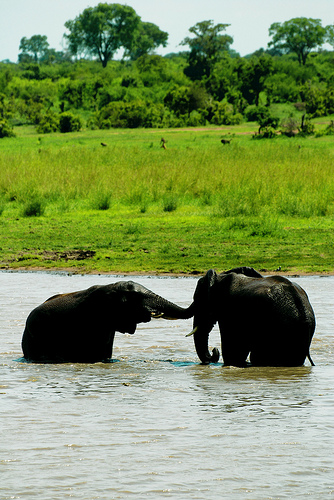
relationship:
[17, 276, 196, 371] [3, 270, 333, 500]
elephant are standing in water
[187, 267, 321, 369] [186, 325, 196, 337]
elephant has tusk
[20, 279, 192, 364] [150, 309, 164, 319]
elephant has tusk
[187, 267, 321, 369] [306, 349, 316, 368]
elephant has a tail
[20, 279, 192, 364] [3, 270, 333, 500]
elephant standing in water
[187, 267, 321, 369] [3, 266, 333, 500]
elephant standing in a river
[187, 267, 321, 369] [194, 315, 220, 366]
elephant has a trunk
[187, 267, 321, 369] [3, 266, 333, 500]
elephant standing in river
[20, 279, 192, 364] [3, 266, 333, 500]
elephant standing in river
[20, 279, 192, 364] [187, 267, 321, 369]
elephant washing or elephant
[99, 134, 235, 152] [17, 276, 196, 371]
animals are nearby elephant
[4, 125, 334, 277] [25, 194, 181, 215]
grass has tufts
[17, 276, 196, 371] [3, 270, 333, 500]
elephant are playing in water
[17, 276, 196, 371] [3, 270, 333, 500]
elephant are half in water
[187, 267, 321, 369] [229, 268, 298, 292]
elephant has a back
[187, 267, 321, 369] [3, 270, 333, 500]
elephant standing in water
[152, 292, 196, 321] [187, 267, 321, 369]
trunk touching elephant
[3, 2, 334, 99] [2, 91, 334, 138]
trees have risen above bushes